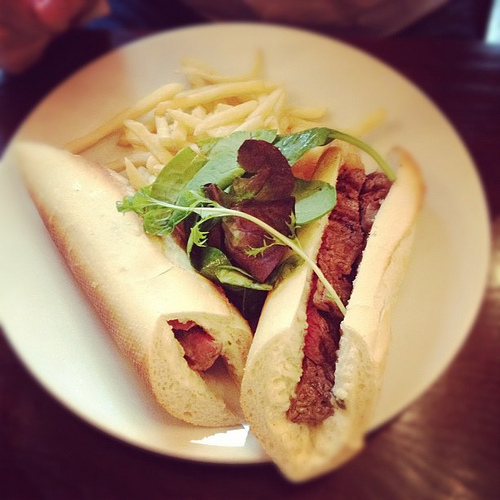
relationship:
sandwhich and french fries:
[6, 132, 261, 432] [159, 89, 221, 132]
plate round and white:
[0, 35, 498, 475] [308, 45, 356, 114]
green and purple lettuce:
[167, 175, 200, 205] [253, 150, 278, 167]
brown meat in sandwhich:
[349, 174, 380, 207] [6, 132, 261, 432]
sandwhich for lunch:
[6, 132, 261, 432] [99, 84, 393, 414]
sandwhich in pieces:
[6, 132, 261, 432] [305, 158, 406, 229]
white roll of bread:
[308, 45, 356, 114] [38, 167, 94, 227]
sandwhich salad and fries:
[6, 132, 261, 432] [159, 89, 221, 132]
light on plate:
[214, 33, 250, 54] [0, 35, 498, 475]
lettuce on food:
[253, 150, 278, 167] [99, 84, 393, 414]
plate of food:
[0, 35, 498, 475] [99, 84, 393, 414]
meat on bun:
[324, 227, 360, 246] [384, 199, 409, 255]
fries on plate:
[159, 89, 221, 132] [0, 35, 498, 475]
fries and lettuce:
[159, 89, 221, 132] [253, 150, 278, 167]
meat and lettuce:
[324, 227, 360, 246] [253, 150, 278, 167]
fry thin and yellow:
[172, 73, 277, 106] [211, 87, 228, 101]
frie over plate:
[72, 128, 116, 148] [0, 35, 498, 475]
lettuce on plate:
[253, 150, 278, 167] [0, 35, 498, 475]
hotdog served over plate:
[305, 158, 406, 229] [0, 35, 498, 475]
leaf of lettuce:
[144, 205, 180, 234] [253, 150, 278, 167]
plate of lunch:
[0, 35, 498, 475] [7, 47, 439, 487]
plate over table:
[0, 35, 498, 475] [423, 32, 473, 82]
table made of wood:
[423, 32, 473, 82] [437, 80, 486, 112]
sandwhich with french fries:
[6, 132, 258, 426] [74, 64, 394, 184]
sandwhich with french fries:
[241, 129, 402, 480] [74, 64, 394, 184]